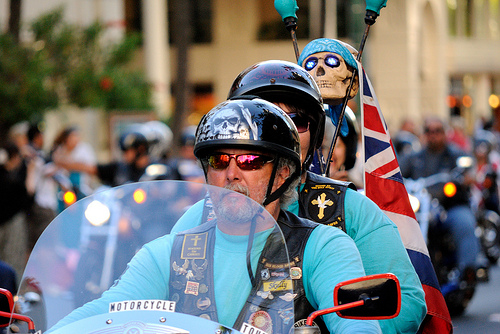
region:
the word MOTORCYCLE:
[105, 297, 175, 308]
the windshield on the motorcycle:
[6, 179, 290, 332]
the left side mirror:
[296, 270, 401, 331]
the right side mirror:
[2, 285, 38, 331]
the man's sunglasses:
[205, 147, 272, 170]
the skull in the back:
[303, 39, 359, 99]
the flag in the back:
[356, 60, 456, 332]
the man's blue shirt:
[58, 211, 360, 331]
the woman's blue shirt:
[297, 170, 426, 332]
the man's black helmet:
[193, 92, 300, 164]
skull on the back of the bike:
[306, 38, 363, 93]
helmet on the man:
[163, 91, 300, 181]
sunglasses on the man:
[185, 143, 270, 181]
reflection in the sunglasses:
[203, 147, 273, 182]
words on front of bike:
[111, 278, 181, 317]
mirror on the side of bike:
[313, 242, 420, 332]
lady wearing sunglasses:
[291, 86, 328, 152]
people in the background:
[19, 103, 111, 184]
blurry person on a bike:
[407, 108, 479, 197]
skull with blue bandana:
[296, 41, 353, 85]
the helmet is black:
[227, 57, 404, 252]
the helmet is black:
[207, 38, 341, 215]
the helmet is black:
[264, 132, 326, 216]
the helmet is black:
[191, 84, 306, 239]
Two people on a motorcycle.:
[24, 54, 434, 332]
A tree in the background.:
[5, 5, 162, 135]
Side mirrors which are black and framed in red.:
[322, 270, 408, 330]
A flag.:
[353, 58, 456, 331]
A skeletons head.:
[291, 25, 367, 105]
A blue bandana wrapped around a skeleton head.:
[291, 35, 364, 69]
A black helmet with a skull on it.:
[181, 84, 313, 172]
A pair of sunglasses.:
[196, 151, 288, 173]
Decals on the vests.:
[161, 182, 345, 330]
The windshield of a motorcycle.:
[8, 167, 301, 331]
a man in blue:
[288, 231, 356, 325]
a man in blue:
[211, 95, 331, 225]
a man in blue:
[254, 77, 372, 324]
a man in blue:
[53, 13, 303, 330]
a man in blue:
[190, 130, 317, 315]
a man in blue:
[210, 215, 263, 310]